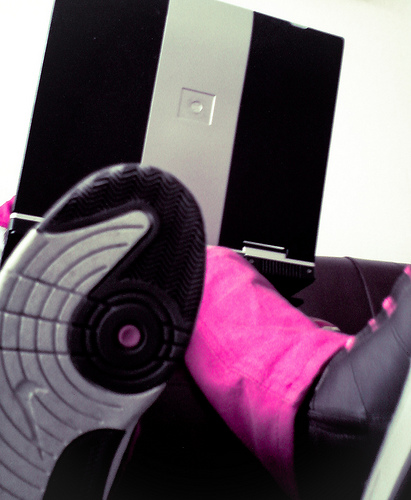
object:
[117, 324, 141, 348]
dot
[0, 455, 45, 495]
lines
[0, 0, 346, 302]
computer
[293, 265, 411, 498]
black shoes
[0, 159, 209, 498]
nike shoe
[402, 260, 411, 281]
lace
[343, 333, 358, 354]
lace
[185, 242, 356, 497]
pants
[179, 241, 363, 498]
leg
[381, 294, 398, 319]
lace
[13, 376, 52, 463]
nike symbol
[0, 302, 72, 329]
line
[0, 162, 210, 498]
bottom